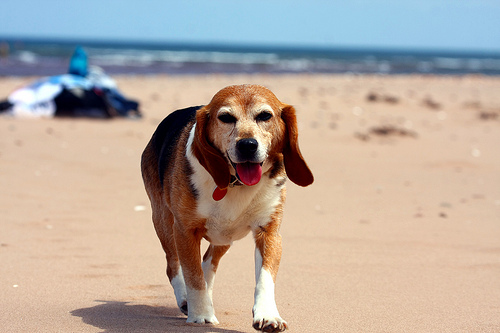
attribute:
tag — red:
[201, 165, 244, 207]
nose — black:
[231, 135, 258, 160]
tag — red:
[212, 183, 229, 200]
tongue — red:
[233, 168, 271, 190]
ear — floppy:
[283, 107, 315, 187]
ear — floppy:
[188, 108, 232, 189]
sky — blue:
[195, 0, 445, 40]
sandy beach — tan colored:
[3, 50, 498, 331]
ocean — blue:
[6, 35, 498, 75]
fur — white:
[258, 277, 273, 315]